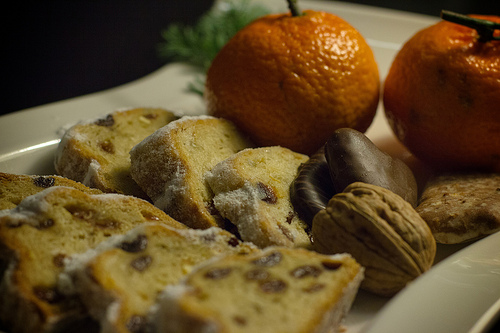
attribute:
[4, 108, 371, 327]
bread — sliced 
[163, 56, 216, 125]
leaves — green 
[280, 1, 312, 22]
stem — small 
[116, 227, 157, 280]
spot — dark 